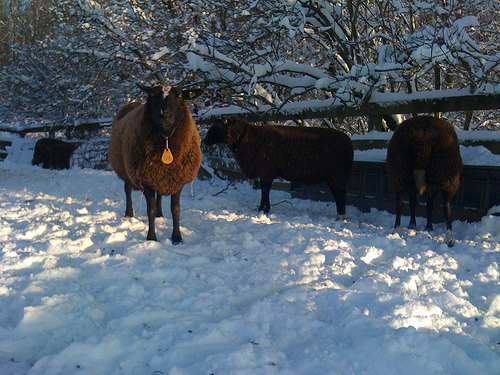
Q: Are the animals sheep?
A: Yes, all the animals are sheep.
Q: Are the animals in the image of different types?
A: No, all the animals are sheep.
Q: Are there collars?
A: Yes, there is a collar.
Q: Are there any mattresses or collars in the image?
A: Yes, there is a collar.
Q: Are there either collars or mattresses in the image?
A: Yes, there is a collar.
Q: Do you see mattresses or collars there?
A: Yes, there is a collar.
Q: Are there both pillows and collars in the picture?
A: No, there is a collar but no pillows.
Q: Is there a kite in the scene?
A: No, there are no kites.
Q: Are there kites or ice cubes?
A: No, there are no kites or ice cubes.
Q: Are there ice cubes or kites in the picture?
A: No, there are no kites or ice cubes.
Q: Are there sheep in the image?
A: Yes, there is a sheep.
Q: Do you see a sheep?
A: Yes, there is a sheep.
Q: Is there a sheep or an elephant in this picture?
A: Yes, there is a sheep.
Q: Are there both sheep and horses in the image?
A: No, there is a sheep but no horses.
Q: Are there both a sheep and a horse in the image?
A: No, there is a sheep but no horses.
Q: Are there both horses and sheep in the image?
A: No, there is a sheep but no horses.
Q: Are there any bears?
A: No, there are no bears.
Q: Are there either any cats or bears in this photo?
A: No, there are no bears or cats.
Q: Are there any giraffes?
A: No, there are no giraffes.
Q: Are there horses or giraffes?
A: No, there are no giraffes or horses.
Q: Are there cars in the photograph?
A: No, there are no cars.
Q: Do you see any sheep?
A: Yes, there is a sheep.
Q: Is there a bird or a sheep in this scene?
A: Yes, there is a sheep.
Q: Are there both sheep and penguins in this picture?
A: No, there is a sheep but no penguins.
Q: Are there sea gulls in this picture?
A: No, there are no sea gulls.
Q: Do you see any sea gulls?
A: No, there are no sea gulls.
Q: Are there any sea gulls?
A: No, there are no sea gulls.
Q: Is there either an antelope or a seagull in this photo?
A: No, there are no seagulls or antelopes.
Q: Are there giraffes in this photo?
A: No, there are no giraffes.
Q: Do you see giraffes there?
A: No, there are no giraffes.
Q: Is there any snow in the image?
A: Yes, there is snow.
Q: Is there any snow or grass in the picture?
A: Yes, there is snow.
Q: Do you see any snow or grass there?
A: Yes, there is snow.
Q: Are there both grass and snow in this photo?
A: No, there is snow but no grass.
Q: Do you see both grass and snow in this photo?
A: No, there is snow but no grass.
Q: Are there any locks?
A: No, there are no locks.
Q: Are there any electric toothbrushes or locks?
A: No, there are no locks or electric toothbrushes.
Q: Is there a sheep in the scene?
A: Yes, there is a sheep.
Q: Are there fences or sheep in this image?
A: Yes, there is a sheep.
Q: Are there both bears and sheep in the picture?
A: No, there is a sheep but no bears.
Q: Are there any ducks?
A: No, there are no ducks.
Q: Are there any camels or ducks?
A: No, there are no ducks or camels.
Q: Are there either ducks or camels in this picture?
A: No, there are no ducks or camels.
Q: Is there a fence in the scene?
A: Yes, there is a fence.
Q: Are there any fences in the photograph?
A: Yes, there is a fence.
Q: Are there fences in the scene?
A: Yes, there is a fence.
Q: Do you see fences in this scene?
A: Yes, there is a fence.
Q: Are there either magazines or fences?
A: Yes, there is a fence.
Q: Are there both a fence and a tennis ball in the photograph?
A: No, there is a fence but no tennis balls.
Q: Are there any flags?
A: No, there are no flags.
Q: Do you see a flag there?
A: No, there are no flags.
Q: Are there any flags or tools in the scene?
A: No, there are no flags or tools.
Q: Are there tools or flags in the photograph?
A: No, there are no flags or tools.